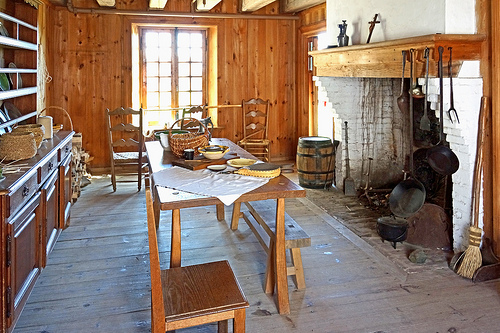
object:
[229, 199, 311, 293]
bench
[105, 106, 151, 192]
chair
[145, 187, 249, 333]
chair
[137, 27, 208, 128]
window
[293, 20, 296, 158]
pole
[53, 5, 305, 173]
wall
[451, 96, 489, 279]
broom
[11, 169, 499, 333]
floor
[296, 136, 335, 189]
barrel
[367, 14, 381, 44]
crucifix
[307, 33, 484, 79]
mantle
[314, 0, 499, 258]
wall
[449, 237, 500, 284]
dust pan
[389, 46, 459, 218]
cooking utensils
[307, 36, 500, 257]
fireplace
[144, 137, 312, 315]
table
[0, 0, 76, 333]
china cabinet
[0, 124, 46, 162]
baskets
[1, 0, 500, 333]
room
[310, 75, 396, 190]
white brick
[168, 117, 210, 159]
basket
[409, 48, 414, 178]
long handle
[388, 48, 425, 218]
pan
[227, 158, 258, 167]
dish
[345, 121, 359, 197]
shovel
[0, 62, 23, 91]
plates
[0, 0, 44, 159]
shelves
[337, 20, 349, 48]
sculpture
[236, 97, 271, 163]
chair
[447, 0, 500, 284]
corner